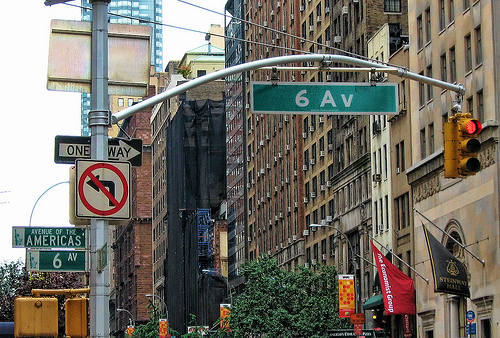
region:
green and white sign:
[248, 75, 405, 122]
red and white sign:
[352, 235, 423, 320]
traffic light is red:
[425, 81, 493, 198]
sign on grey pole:
[102, 47, 370, 131]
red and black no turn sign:
[60, 157, 134, 221]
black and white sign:
[65, 130, 143, 171]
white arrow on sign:
[61, 131, 141, 172]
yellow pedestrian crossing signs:
[20, 270, 104, 325]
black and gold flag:
[402, 220, 486, 300]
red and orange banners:
[330, 255, 365, 320]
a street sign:
[251, 83, 393, 114]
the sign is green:
[254, 85, 399, 113]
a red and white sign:
[74, 159, 131, 214]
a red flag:
[373, 253, 415, 316]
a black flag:
[425, 221, 473, 298]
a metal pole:
[87, 42, 110, 113]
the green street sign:
[11, 224, 83, 254]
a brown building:
[241, 125, 307, 240]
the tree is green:
[250, 273, 325, 327]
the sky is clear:
[14, 103, 51, 145]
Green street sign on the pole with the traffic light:
[246, 74, 403, 119]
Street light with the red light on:
[439, 104, 485, 185]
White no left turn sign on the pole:
[70, 154, 137, 224]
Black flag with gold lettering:
[419, 221, 474, 300]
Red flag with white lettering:
[365, 233, 418, 318]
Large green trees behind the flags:
[190, 242, 357, 336]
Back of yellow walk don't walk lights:
[7, 283, 94, 336]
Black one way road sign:
[50, 129, 146, 170]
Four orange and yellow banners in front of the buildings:
[123, 271, 360, 337]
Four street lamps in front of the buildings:
[114, 218, 363, 337]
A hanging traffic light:
[441, 107, 482, 180]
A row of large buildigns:
[108, 1, 498, 336]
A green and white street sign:
[246, 76, 399, 115]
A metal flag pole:
[412, 205, 484, 265]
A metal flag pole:
[366, 235, 427, 281]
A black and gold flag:
[419, 223, 471, 295]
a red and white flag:
[368, 242, 416, 312]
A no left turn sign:
[76, 156, 134, 221]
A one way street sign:
[53, 132, 144, 168]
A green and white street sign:
[13, 225, 88, 250]